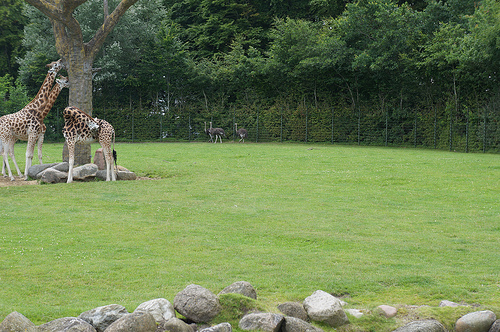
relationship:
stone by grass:
[455, 306, 498, 331] [4, 142, 500, 310]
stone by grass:
[437, 299, 474, 317] [4, 142, 500, 310]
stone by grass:
[301, 290, 347, 322] [4, 142, 500, 310]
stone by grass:
[177, 281, 225, 322] [4, 142, 500, 310]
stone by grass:
[227, 279, 259, 304] [4, 142, 500, 310]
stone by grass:
[134, 295, 177, 332] [4, 142, 500, 310]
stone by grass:
[36, 315, 102, 331] [4, 142, 500, 310]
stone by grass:
[239, 307, 287, 332] [4, 142, 500, 310]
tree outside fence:
[179, 0, 258, 143] [1, 97, 499, 151]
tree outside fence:
[282, 11, 339, 141] [1, 97, 499, 151]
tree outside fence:
[385, 3, 435, 149] [1, 97, 499, 151]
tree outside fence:
[427, 4, 492, 151] [1, 97, 499, 151]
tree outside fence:
[348, 3, 411, 144] [1, 97, 499, 151]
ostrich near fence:
[206, 120, 228, 142] [1, 97, 499, 151]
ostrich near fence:
[229, 124, 252, 144] [1, 97, 499, 151]